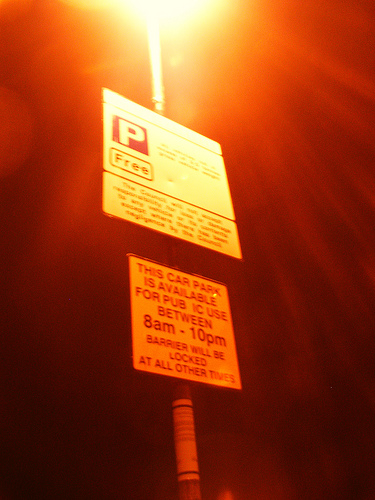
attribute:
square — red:
[49, 44, 317, 266]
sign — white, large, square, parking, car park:
[91, 84, 249, 265]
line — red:
[153, 185, 180, 201]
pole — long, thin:
[131, 8, 174, 94]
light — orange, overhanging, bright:
[112, 1, 214, 30]